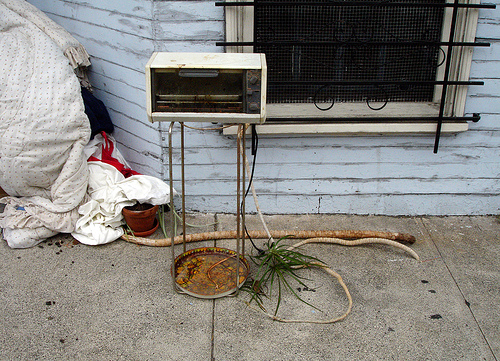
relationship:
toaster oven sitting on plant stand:
[146, 51, 269, 125] [168, 121, 251, 300]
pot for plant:
[123, 203, 160, 236] [248, 234, 329, 321]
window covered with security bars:
[225, 2, 480, 137] [214, 0, 498, 156]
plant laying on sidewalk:
[248, 234, 329, 321] [1, 212, 498, 360]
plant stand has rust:
[168, 121, 251, 300] [236, 124, 248, 176]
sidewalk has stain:
[1, 212, 498, 360] [430, 313, 442, 321]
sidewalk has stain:
[1, 212, 498, 360] [427, 287, 436, 294]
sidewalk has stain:
[1, 212, 498, 360] [420, 276, 429, 285]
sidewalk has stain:
[1, 212, 498, 360] [386, 326, 395, 334]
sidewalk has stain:
[1, 212, 498, 360] [60, 337, 66, 344]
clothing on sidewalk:
[2, 2, 179, 246] [1, 212, 498, 360]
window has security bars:
[225, 2, 480, 137] [214, 0, 498, 156]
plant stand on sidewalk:
[168, 121, 251, 300] [1, 212, 498, 360]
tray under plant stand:
[170, 245, 252, 299] [168, 121, 251, 300]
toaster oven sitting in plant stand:
[146, 51, 269, 125] [168, 121, 251, 300]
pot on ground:
[123, 203, 160, 236] [1, 212, 498, 360]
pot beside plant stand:
[123, 203, 160, 236] [168, 121, 251, 300]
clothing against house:
[2, 2, 179, 246] [26, 0, 500, 219]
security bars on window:
[214, 0, 498, 156] [225, 2, 480, 137]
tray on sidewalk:
[170, 245, 252, 299] [1, 212, 498, 360]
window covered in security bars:
[225, 2, 480, 137] [214, 0, 498, 156]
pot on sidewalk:
[123, 203, 160, 236] [1, 212, 498, 360]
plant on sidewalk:
[248, 234, 329, 321] [1, 212, 498, 360]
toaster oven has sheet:
[146, 51, 269, 125] [156, 85, 243, 102]